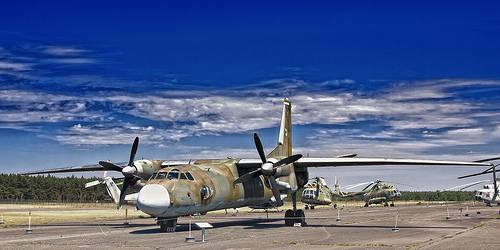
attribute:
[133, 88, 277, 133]
clouds — white, menacing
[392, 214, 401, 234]
pole — white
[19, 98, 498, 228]
rust — small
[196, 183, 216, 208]
plane — discolored, white, old, rusty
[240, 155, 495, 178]
wing — white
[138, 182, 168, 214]
nose — white, pointy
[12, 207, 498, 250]
pavement — gray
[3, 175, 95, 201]
trees — green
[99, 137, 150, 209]
propeller — rusty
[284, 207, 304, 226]
wheels — rear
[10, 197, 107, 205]
fence — small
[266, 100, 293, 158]
tail — dirty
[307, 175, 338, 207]
helicopter — discolored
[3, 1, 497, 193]
sky — cloudy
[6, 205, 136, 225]
grass — dry